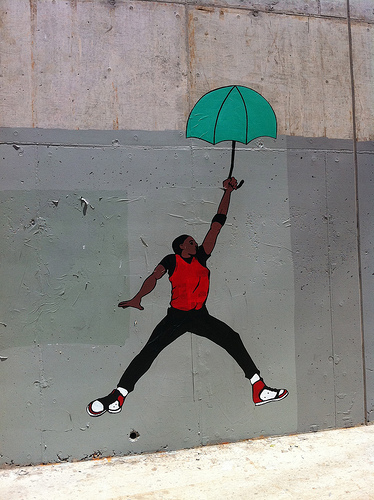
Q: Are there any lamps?
A: No, there are no lamps.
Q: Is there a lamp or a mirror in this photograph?
A: No, there are no lamps or mirrors.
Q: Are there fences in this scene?
A: No, there are no fences.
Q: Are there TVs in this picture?
A: No, there are no tvs.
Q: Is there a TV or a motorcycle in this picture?
A: No, there are no televisions or motorcycles.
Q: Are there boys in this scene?
A: No, there are no boys.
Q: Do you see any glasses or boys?
A: No, there are no boys or glasses.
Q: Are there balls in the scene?
A: No, there are no balls.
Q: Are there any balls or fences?
A: No, there are no balls or fences.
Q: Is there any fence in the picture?
A: No, there are no fences.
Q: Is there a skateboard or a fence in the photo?
A: No, there are no fences or skateboards.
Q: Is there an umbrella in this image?
A: Yes, there is an umbrella.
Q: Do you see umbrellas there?
A: Yes, there is an umbrella.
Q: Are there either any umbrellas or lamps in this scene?
A: Yes, there is an umbrella.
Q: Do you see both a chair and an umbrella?
A: No, there is an umbrella but no chairs.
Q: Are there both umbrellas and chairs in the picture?
A: No, there is an umbrella but no chairs.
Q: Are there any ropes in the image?
A: No, there are no ropes.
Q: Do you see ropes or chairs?
A: No, there are no ropes or chairs.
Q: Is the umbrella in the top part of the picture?
A: Yes, the umbrella is in the top of the image.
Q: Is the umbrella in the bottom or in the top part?
A: The umbrella is in the top of the image.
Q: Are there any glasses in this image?
A: No, there are no glasses.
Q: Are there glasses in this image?
A: No, there are no glasses.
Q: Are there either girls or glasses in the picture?
A: No, there are no glasses or girls.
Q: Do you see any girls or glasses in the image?
A: No, there are no glasses or girls.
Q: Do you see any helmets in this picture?
A: No, there are no helmets.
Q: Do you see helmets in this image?
A: No, there are no helmets.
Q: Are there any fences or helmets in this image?
A: No, there are no helmets or fences.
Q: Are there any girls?
A: No, there are no girls.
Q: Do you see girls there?
A: No, there are no girls.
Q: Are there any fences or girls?
A: No, there are no girls or fences.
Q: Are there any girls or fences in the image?
A: No, there are no girls or fences.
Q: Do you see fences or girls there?
A: No, there are no girls or fences.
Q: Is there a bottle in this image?
A: No, there are no bottles.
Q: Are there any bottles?
A: No, there are no bottles.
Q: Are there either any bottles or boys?
A: No, there are no bottles or boys.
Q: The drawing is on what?
A: The drawing is on the wall.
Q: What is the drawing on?
A: The drawing is on the wall.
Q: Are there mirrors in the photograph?
A: No, there are no mirrors.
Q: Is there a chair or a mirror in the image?
A: No, there are no mirrors or chairs.